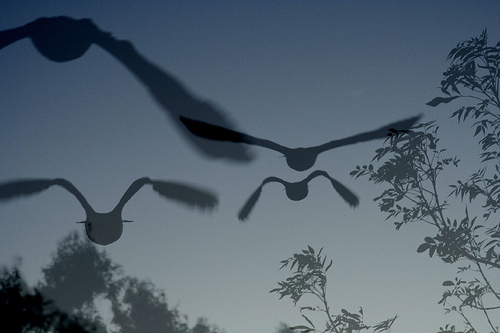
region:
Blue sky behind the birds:
[253, 36, 366, 104]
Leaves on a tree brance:
[375, 164, 499, 235]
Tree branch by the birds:
[316, 296, 336, 332]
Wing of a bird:
[123, 170, 224, 208]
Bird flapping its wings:
[183, 116, 413, 151]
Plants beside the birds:
[433, 62, 497, 332]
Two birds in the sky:
[186, 113, 393, 210]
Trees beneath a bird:
[51, 259, 176, 329]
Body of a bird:
[285, 181, 306, 197]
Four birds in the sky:
[2, 14, 427, 238]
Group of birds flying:
[7, 10, 385, 285]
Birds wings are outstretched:
[161, 83, 428, 168]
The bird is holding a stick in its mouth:
[68, 212, 148, 247]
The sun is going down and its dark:
[212, 26, 364, 106]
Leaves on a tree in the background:
[388, 93, 485, 219]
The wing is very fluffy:
[141, 155, 196, 209]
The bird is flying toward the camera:
[0, 10, 217, 168]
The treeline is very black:
[4, 260, 116, 328]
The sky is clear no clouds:
[232, 20, 329, 85]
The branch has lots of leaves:
[277, 214, 345, 326]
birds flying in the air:
[8, 16, 494, 323]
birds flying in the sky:
[30, 9, 444, 281]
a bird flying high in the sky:
[16, 12, 435, 304]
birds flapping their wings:
[29, 10, 499, 302]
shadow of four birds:
[9, 10, 489, 309]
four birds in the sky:
[17, 10, 462, 293]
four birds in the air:
[8, 10, 451, 277]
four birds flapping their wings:
[10, 2, 430, 299]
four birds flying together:
[5, 7, 454, 285]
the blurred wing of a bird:
[0, 177, 40, 197]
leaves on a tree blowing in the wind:
[269, 245, 331, 301]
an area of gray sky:
[197, 230, 229, 275]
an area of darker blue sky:
[231, 5, 395, 66]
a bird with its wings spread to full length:
[177, 112, 422, 172]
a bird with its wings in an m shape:
[235, 169, 361, 221]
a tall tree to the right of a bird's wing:
[350, 26, 499, 329]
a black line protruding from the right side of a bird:
[122, 217, 136, 222]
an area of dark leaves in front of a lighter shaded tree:
[1, 268, 97, 331]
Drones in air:
[2, 10, 465, 272]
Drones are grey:
[179, 89, 408, 226]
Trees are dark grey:
[262, 222, 422, 331]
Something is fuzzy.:
[11, 227, 205, 331]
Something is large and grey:
[13, 217, 240, 327]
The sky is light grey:
[180, 25, 375, 110]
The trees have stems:
[343, 125, 489, 310]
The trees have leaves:
[320, 88, 480, 283]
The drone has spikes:
[41, 216, 146, 237]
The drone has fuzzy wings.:
[137, 166, 234, 227]